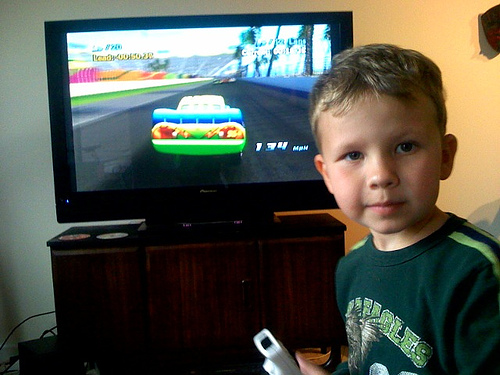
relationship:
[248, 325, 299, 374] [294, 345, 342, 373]
remote in hand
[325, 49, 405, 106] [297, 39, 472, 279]
hair on boy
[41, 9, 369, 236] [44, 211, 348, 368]
tv on stand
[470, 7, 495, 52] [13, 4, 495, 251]
light on wall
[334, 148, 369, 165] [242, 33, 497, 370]
eye of boy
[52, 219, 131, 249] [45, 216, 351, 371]
discs on counter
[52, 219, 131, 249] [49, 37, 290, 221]
discs by tv